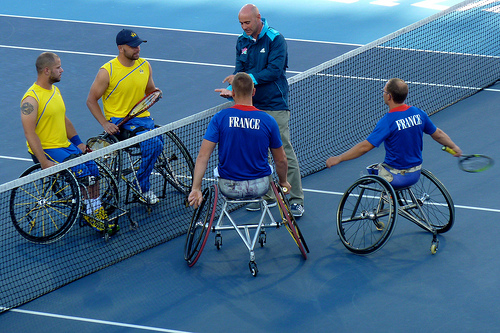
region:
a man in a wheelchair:
[324, 73, 464, 255]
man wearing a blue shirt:
[370, 105, 437, 167]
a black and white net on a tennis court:
[3, 0, 499, 309]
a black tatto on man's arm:
[20, 100, 35, 117]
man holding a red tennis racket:
[106, 90, 160, 135]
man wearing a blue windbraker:
[228, 17, 291, 112]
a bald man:
[238, 4, 260, 37]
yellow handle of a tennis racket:
[442, 145, 458, 162]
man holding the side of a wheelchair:
[183, 73, 308, 274]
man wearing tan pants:
[263, 108, 302, 205]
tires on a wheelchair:
[333, 182, 393, 253]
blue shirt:
[225, 146, 260, 169]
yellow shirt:
[38, 110, 68, 142]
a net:
[10, 200, 75, 255]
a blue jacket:
[255, 50, 286, 83]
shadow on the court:
[317, 258, 377, 312]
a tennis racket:
[464, 144, 489, 178]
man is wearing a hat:
[115, 28, 158, 46]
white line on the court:
[98, 311, 137, 331]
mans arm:
[270, 150, 299, 186]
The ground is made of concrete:
[140, 278, 463, 326]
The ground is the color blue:
[125, 278, 475, 330]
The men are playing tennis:
[0, 0, 495, 292]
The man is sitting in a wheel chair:
[176, 66, 328, 288]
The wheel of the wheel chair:
[267, 178, 324, 260]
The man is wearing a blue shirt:
[366, 108, 439, 168]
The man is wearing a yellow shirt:
[17, 77, 72, 151]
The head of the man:
[224, 70, 261, 109]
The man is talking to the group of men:
[213, 1, 322, 224]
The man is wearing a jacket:
[222, 17, 297, 114]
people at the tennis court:
[18, 21, 470, 293]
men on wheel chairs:
[13, 27, 361, 295]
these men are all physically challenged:
[7, 25, 475, 278]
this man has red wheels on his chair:
[191, 174, 321, 279]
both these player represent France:
[203, 110, 430, 194]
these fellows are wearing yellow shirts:
[18, 45, 168, 154]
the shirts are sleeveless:
[24, 58, 159, 153]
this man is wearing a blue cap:
[100, 23, 153, 70]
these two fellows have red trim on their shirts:
[224, 96, 439, 154]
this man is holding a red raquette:
[113, 83, 173, 133]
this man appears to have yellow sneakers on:
[81, 201, 124, 246]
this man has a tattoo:
[7, 86, 40, 120]